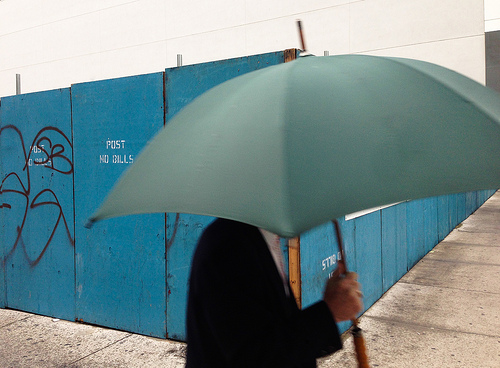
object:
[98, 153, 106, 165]
letter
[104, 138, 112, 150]
letter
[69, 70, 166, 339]
wall board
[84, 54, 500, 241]
umbrella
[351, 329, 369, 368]
handle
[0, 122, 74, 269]
graffiti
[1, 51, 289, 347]
wall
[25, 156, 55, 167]
writing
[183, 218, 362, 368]
man